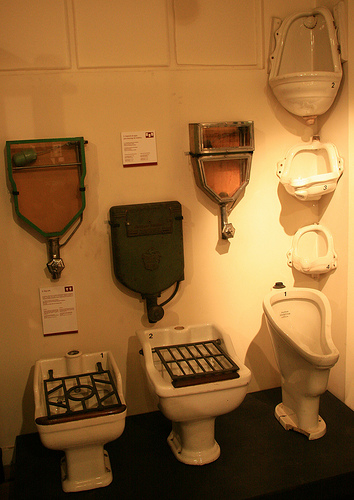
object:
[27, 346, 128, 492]
toilet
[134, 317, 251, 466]
toilet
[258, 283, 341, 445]
toilet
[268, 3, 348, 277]
fixtures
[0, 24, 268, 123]
wall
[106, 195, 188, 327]
tank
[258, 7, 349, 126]
urnial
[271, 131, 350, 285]
urinals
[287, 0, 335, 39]
corner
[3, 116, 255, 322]
tanks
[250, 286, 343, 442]
urinal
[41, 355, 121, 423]
part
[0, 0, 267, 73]
panels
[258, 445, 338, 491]
box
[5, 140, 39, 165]
thing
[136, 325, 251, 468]
toilet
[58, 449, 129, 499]
base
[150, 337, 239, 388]
seat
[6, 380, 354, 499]
floor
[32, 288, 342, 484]
toilets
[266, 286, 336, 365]
bowl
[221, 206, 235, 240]
flush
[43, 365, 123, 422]
grid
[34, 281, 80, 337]
sign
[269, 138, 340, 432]
toilets